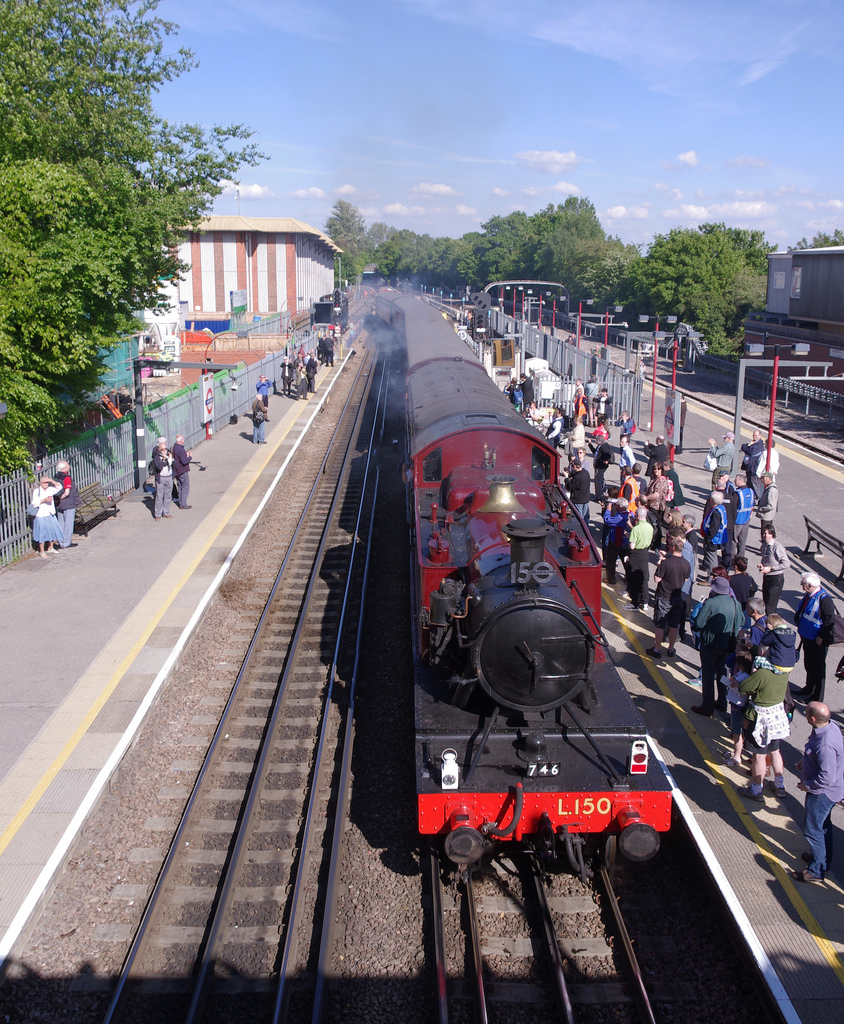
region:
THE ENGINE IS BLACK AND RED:
[352, 276, 704, 883]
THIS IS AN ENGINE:
[382, 342, 690, 856]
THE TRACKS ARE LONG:
[26, 284, 684, 1018]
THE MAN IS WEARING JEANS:
[795, 789, 835, 899]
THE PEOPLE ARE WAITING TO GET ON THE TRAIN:
[488, 350, 838, 929]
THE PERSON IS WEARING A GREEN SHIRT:
[731, 664, 788, 721]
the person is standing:
[649, 540, 686, 606]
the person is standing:
[799, 680, 835, 871]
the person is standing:
[745, 658, 800, 780]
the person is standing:
[749, 433, 809, 528]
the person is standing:
[598, 430, 616, 499]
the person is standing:
[622, 502, 673, 632]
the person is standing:
[18, 471, 67, 550]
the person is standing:
[138, 441, 165, 520]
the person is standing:
[566, 380, 608, 439]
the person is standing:
[753, 528, 791, 600]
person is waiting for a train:
[149, 434, 175, 514]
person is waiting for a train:
[53, 458, 77, 544]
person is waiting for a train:
[25, 477, 61, 555]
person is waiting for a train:
[249, 395, 265, 443]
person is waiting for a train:
[746, 655, 791, 793]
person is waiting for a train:
[794, 697, 842, 877]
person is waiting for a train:
[695, 573, 742, 711]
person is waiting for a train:
[652, 540, 694, 653]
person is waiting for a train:
[153, 443, 177, 512]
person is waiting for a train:
[25, 471, 64, 552]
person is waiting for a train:
[170, 434, 207, 508]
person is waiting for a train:
[248, 392, 269, 443]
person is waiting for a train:
[698, 577, 740, 709]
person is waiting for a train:
[740, 657, 791, 793]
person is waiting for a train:
[762, 607, 800, 672]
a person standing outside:
[728, 563, 761, 666]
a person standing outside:
[764, 609, 819, 765]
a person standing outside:
[639, 573, 733, 688]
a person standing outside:
[624, 512, 679, 591]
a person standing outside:
[713, 544, 770, 654]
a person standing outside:
[655, 435, 698, 529]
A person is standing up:
[683, 563, 758, 718]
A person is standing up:
[644, 540, 676, 653]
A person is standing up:
[680, 512, 696, 567]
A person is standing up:
[695, 482, 733, 573]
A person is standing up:
[716, 472, 766, 574]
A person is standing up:
[758, 467, 783, 534]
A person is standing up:
[743, 517, 775, 602]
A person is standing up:
[779, 570, 832, 685]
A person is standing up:
[797, 699, 837, 876]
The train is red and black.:
[421, 463, 692, 847]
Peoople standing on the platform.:
[574, 428, 815, 747]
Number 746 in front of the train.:
[516, 747, 578, 784]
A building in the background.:
[145, 196, 352, 329]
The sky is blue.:
[212, 29, 701, 188]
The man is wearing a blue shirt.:
[802, 734, 841, 793]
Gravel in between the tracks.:
[324, 774, 437, 1006]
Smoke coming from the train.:
[340, 284, 425, 444]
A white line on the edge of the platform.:
[31, 694, 100, 906]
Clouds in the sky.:
[498, 142, 787, 232]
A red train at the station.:
[366, 273, 669, 862]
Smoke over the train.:
[372, 273, 472, 492]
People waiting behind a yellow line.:
[58, 311, 331, 596]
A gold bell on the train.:
[461, 460, 539, 526]